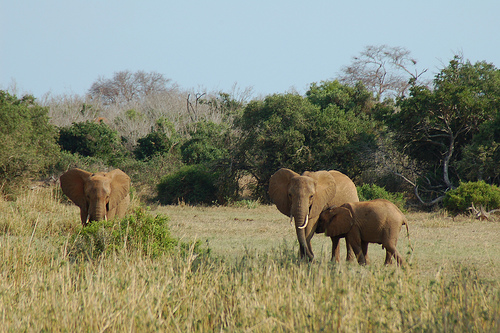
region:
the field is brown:
[42, 265, 433, 330]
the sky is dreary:
[60, 12, 329, 57]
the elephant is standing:
[52, 161, 140, 224]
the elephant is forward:
[51, 157, 131, 227]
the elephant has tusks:
[280, 208, 318, 238]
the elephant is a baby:
[327, 193, 428, 274]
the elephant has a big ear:
[267, 163, 290, 229]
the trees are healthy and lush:
[259, 97, 356, 144]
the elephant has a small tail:
[399, 210, 421, 245]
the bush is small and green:
[72, 208, 190, 252]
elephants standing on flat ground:
[28, 125, 449, 321]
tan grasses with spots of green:
[31, 241, 446, 327]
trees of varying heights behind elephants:
[20, 40, 485, 247]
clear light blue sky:
[57, 12, 322, 52]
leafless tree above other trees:
[336, 36, 416, 97]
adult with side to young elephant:
[255, 156, 426, 276]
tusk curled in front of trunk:
[270, 172, 315, 257]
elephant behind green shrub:
[37, 147, 152, 262]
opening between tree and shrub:
[197, 150, 263, 211]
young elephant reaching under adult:
[275, 168, 425, 274]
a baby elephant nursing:
[312, 198, 413, 263]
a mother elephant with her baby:
[262, 160, 362, 260]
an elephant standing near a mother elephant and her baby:
[55, 156, 136, 255]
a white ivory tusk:
[293, 208, 313, 233]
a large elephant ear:
[264, 163, 299, 225]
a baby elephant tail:
[401, 219, 414, 244]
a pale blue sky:
[0, 3, 497, 113]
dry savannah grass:
[2, 195, 491, 331]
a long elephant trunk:
[291, 206, 317, 265]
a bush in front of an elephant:
[79, 203, 187, 253]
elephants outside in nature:
[20, 118, 441, 301]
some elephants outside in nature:
[38, 133, 428, 303]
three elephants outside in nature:
[43, 113, 438, 298]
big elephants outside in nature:
[35, 118, 432, 288]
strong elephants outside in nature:
[19, 123, 438, 291]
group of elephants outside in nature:
[17, 126, 439, 304]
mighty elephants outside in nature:
[45, 93, 451, 292]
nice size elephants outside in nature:
[39, 123, 431, 299]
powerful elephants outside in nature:
[32, 99, 442, 294]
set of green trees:
[200, 86, 475, 165]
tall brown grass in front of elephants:
[27, 259, 487, 325]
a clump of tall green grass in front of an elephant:
[81, 220, 177, 257]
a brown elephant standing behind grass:
[64, 166, 132, 218]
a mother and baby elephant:
[258, 158, 415, 250]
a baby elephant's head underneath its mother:
[314, 206, 349, 239]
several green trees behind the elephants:
[20, 90, 492, 153]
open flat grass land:
[192, 210, 272, 252]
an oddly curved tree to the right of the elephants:
[413, 142, 457, 212]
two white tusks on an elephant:
[281, 212, 315, 232]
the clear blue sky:
[208, 7, 279, 85]